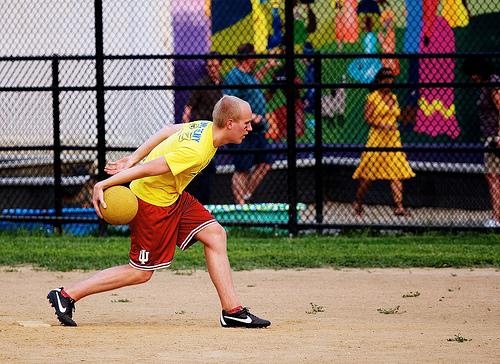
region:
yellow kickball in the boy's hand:
[85, 167, 153, 242]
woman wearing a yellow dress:
[335, 55, 424, 225]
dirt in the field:
[274, 272, 411, 342]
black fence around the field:
[271, 13, 443, 205]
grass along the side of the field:
[283, 231, 433, 265]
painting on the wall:
[217, 11, 467, 122]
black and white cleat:
[213, 295, 274, 331]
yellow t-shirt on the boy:
[123, 116, 220, 206]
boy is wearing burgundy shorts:
[131, 198, 215, 265]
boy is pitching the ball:
[46, 73, 285, 353]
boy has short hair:
[219, 91, 254, 124]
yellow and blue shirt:
[140, 123, 229, 209]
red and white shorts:
[124, 196, 213, 265]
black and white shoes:
[217, 300, 277, 335]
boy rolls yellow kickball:
[75, 166, 141, 233]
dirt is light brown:
[254, 268, 389, 359]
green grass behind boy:
[168, 234, 353, 253]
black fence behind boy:
[107, 38, 389, 218]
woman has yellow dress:
[325, 46, 437, 217]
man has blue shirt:
[230, 66, 269, 132]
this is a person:
[44, 79, 299, 340]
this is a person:
[338, 49, 433, 249]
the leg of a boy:
[177, 150, 273, 353]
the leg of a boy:
[39, 208, 186, 346]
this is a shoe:
[207, 291, 268, 344]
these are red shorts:
[109, 176, 229, 269]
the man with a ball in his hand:
[45, 95, 271, 326]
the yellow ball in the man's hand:
[98, 185, 138, 226]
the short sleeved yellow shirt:
[130, 120, 217, 205]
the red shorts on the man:
[125, 177, 215, 268]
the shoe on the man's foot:
[220, 306, 271, 328]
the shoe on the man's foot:
[46, 286, 76, 326]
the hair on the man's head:
[211, 94, 249, 127]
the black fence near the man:
[0, 0, 498, 235]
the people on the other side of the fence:
[182, 42, 499, 227]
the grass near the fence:
[0, 225, 498, 276]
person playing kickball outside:
[79, 63, 264, 362]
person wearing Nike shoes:
[41, 280, 278, 337]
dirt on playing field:
[20, 256, 453, 361]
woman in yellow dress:
[358, 51, 418, 222]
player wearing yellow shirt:
[140, 88, 248, 204]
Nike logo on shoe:
[217, 309, 253, 329]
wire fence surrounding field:
[53, 23, 359, 108]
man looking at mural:
[227, 43, 267, 103]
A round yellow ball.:
[97, 186, 144, 223]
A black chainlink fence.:
[2, 0, 499, 233]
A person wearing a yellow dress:
[357, 65, 418, 225]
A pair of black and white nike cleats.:
[49, 287, 269, 328]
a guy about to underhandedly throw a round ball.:
[57, 97, 290, 333]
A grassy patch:
[7, 227, 499, 267]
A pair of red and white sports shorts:
[125, 192, 212, 269]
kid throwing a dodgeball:
[36, 88, 281, 333]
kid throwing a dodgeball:
[45, 83, 280, 331]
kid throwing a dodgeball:
[45, 82, 288, 329]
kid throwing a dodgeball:
[45, 79, 287, 334]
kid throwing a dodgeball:
[45, 88, 280, 330]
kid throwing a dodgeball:
[41, 80, 277, 336]